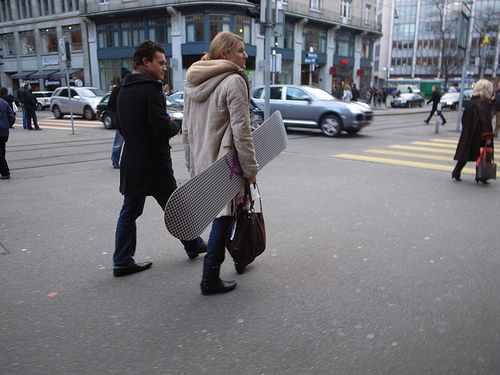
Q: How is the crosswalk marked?
A: Yellow lines.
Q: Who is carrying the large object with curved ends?
A: Blond woman.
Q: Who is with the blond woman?
A: Man in black coat.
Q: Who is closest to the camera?
A: Blond woman with the large object in her right hand.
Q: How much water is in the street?
A: It is dry.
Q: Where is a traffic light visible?
A: Far corner.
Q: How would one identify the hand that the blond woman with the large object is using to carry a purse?
A: Right hand.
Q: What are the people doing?
A: Walking.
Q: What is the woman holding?
A: A snowboard.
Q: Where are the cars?
A: At the intersection.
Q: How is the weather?
A: Chilly.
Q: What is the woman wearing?
A: A large coat.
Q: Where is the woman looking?
A: To the right.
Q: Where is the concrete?
A: On the ground.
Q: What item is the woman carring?
A: A snowboard.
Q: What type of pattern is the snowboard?
A: Checkered.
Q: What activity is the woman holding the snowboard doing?
A: Walking.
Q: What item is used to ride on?
A: A snowboard.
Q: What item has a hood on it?
A: A jacket.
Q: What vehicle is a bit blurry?
A: A SUV.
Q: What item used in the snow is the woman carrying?
A: A snowboard.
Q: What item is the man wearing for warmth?
A: A jacket.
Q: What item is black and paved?
A: The road.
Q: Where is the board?
A: Under her arm.